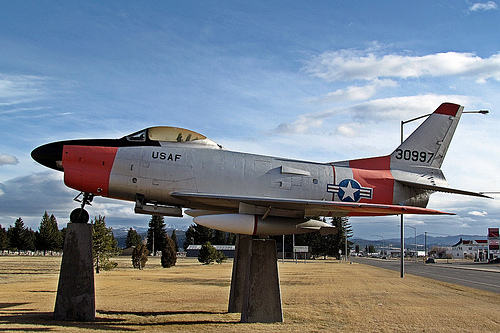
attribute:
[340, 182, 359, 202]
star — white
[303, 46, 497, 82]
cloud — white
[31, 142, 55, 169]
nose tip — black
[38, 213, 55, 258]
tree — tall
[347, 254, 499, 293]
road — wide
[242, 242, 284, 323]
column — concrete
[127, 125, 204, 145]
dome — cockpit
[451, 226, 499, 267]
town — small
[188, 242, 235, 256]
barn — metal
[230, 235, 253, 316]
post — cement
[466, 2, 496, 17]
cloud — white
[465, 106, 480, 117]
post — horizontal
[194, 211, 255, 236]
nose — white